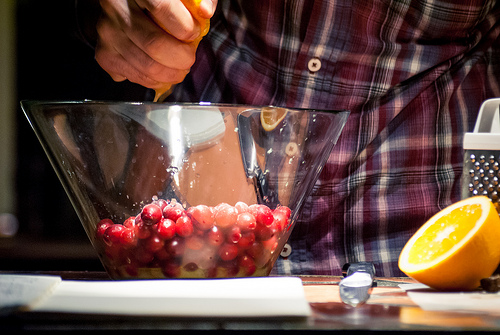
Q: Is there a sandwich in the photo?
A: No, there are no sandwiches.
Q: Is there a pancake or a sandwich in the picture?
A: No, there are no sandwiches or pancakes.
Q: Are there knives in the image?
A: Yes, there is a knife.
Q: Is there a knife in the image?
A: Yes, there is a knife.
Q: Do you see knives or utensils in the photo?
A: Yes, there is a knife.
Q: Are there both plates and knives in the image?
A: No, there is a knife but no plates.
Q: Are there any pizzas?
A: No, there are no pizzas.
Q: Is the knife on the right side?
A: Yes, the knife is on the right of the image.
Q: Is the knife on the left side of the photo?
A: No, the knife is on the right of the image.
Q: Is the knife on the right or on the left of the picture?
A: The knife is on the right of the image.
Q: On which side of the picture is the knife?
A: The knife is on the right of the image.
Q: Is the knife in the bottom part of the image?
A: Yes, the knife is in the bottom of the image.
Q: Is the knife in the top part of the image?
A: No, the knife is in the bottom of the image.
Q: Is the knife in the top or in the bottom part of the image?
A: The knife is in the bottom of the image.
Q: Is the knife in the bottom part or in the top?
A: The knife is in the bottom of the image.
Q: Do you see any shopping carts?
A: No, there are no shopping carts.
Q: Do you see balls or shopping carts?
A: No, there are no shopping carts or balls.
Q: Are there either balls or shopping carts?
A: No, there are no shopping carts or balls.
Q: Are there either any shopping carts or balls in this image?
A: No, there are no shopping carts or balls.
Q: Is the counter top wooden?
A: Yes, the counter top is wooden.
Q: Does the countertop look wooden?
A: Yes, the countertop is wooden.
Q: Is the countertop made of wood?
A: Yes, the countertop is made of wood.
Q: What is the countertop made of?
A: The countertop is made of wood.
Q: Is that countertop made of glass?
A: No, the countertop is made of wood.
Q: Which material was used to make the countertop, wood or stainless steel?
A: The countertop is made of wood.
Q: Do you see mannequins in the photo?
A: No, there are no mannequins.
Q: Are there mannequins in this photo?
A: No, there are no mannequins.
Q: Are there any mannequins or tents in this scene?
A: No, there are no mannequins or tents.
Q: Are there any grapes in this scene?
A: Yes, there are grapes.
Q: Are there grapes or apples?
A: Yes, there are grapes.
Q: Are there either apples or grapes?
A: Yes, there are grapes.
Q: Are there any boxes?
A: No, there are no boxes.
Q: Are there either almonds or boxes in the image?
A: No, there are no boxes or almonds.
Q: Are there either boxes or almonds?
A: No, there are no boxes or almonds.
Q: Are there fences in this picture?
A: No, there are no fences.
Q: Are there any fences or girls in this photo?
A: No, there are no fences or girls.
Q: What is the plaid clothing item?
A: The clothing item is a shirt.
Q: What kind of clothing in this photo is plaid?
A: The clothing is a shirt.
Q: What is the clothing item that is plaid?
A: The clothing item is a shirt.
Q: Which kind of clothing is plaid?
A: The clothing is a shirt.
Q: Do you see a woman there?
A: No, there are no women.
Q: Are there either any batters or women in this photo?
A: No, there are no women or batters.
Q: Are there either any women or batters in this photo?
A: No, there are no women or batters.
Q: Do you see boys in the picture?
A: No, there are no boys.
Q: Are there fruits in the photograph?
A: Yes, there is a fruit.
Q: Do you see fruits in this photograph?
A: Yes, there is a fruit.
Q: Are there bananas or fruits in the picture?
A: Yes, there is a fruit.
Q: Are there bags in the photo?
A: No, there are no bags.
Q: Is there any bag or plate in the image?
A: No, there are no bags or plates.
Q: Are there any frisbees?
A: No, there are no frisbees.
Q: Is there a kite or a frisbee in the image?
A: No, there are no frisbees or kites.